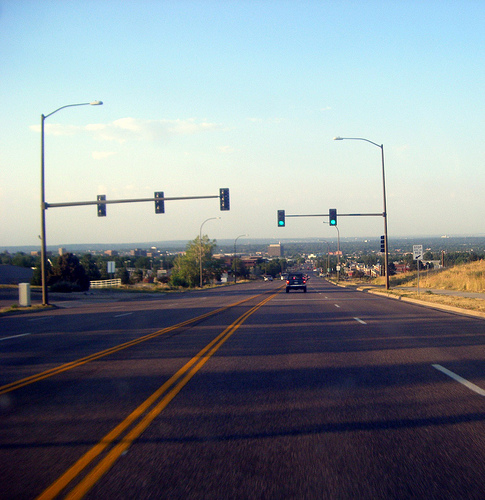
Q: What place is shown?
A: It is a road.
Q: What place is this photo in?
A: It is at the road.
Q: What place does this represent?
A: It represents the road.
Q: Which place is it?
A: It is a road.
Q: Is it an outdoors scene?
A: Yes, it is outdoors.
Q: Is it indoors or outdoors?
A: It is outdoors.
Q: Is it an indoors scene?
A: No, it is outdoors.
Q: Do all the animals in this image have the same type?
A: Yes, all the animals are zebras.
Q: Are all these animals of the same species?
A: Yes, all the animals are zebras.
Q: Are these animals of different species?
A: No, all the animals are zebras.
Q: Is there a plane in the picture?
A: No, there are no airplanes.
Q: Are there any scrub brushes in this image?
A: No, there are no scrub brushes.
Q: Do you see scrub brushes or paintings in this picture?
A: No, there are no scrub brushes or paintings.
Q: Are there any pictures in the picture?
A: No, there are no pictures.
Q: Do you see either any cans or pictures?
A: No, there are no pictures or cans.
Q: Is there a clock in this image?
A: No, there are no clocks.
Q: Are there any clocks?
A: No, there are no clocks.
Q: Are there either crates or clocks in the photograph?
A: No, there are no clocks or crates.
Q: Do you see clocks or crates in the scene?
A: No, there are no clocks or crates.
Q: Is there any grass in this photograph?
A: Yes, there is grass.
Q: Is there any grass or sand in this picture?
A: Yes, there is grass.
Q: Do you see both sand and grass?
A: No, there is grass but no sand.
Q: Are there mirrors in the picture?
A: No, there are no mirrors.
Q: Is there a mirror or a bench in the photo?
A: No, there are no mirrors or benches.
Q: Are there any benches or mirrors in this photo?
A: No, there are no mirrors or benches.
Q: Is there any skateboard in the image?
A: No, there are no skateboards.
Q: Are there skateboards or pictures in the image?
A: No, there are no skateboards or pictures.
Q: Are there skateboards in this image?
A: No, there are no skateboards.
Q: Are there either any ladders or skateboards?
A: No, there are no skateboards or ladders.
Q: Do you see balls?
A: No, there are no balls.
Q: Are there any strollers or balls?
A: No, there are no balls or strollers.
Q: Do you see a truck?
A: No, there are no trucks.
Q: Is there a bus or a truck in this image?
A: No, there are no trucks or buses.